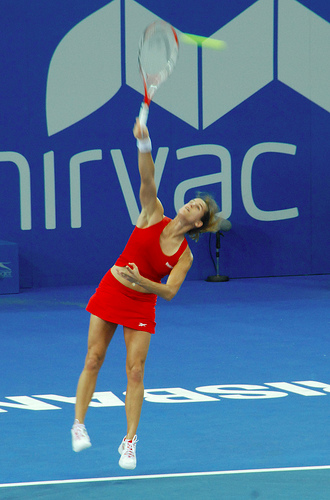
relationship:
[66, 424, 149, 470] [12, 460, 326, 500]
feet are off ground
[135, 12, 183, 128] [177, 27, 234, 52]
racquet hitting ball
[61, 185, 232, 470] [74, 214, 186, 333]
woman wearing an outfit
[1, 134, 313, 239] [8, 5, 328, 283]
words on wall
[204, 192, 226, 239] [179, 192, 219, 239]
hair pulled back on head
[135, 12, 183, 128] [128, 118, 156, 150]
racquet in hand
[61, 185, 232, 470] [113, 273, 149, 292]
woman showing midriff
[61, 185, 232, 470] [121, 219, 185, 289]
woman wearing a shirt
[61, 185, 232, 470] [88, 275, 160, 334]
woman wearing a skirt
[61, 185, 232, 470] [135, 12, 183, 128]
woman holding racquet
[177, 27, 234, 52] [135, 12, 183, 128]
ball next to racquet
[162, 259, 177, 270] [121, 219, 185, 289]
symbol on shirt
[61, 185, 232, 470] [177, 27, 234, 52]
woman looking at ball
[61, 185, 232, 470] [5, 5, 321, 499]
woman playing tennis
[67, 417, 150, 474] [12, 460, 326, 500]
shoes are off ground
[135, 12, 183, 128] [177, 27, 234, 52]
racquet hitting a ball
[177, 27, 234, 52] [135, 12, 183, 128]
ball moving away from racquet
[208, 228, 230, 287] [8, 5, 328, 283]
stand near wall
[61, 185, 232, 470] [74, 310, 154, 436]
woman has legs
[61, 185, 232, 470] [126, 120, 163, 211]
woman has arm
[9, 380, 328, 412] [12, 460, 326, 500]
letters are on ground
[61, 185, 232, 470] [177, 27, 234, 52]
woman hitting a ball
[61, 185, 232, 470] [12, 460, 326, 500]
woman off ground